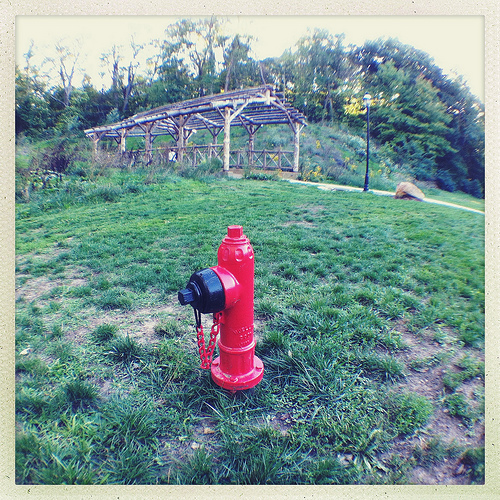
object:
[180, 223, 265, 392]
hydrant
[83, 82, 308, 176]
bridge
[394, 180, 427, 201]
rock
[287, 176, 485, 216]
path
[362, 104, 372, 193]
lamp post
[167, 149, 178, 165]
person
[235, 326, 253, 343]
imprint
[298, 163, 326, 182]
bush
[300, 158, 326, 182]
flower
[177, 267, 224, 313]
cap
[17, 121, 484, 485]
field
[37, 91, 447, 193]
hill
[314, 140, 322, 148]
flower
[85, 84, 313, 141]
roof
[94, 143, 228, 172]
guardrail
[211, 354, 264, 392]
base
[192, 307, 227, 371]
chain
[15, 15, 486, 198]
tree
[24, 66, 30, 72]
leaf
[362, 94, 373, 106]
lamp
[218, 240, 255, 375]
tank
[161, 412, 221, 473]
dirt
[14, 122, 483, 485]
grass